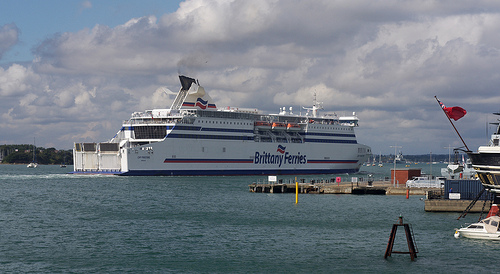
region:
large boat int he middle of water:
[25, 37, 495, 272]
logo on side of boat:
[226, 136, 316, 175]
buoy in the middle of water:
[368, 198, 443, 269]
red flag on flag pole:
[426, 84, 480, 159]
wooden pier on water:
[268, 166, 435, 211]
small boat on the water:
[446, 201, 499, 266]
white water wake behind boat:
[1, 161, 142, 214]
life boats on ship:
[247, 121, 317, 148]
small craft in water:
[7, 155, 50, 179]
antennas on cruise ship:
[279, 76, 339, 122]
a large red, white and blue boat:
[57, 74, 374, 177]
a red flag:
[440, 102, 470, 119]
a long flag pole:
[432, 95, 474, 147]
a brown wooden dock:
[244, 177, 388, 192]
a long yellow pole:
[293, 180, 301, 206]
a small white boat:
[454, 214, 499, 240]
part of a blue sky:
[8, 0, 163, 19]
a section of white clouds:
[0, 62, 111, 142]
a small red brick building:
[390, 167, 420, 186]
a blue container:
[442, 178, 489, 198]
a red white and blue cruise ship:
[82, 75, 369, 177]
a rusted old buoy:
[378, 205, 420, 267]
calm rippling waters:
[83, 194, 265, 266]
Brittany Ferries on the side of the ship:
[249, 137, 321, 167]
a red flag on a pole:
[421, 85, 476, 142]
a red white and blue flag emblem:
[272, 140, 286, 153]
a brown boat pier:
[249, 169, 399, 197]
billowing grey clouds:
[12, 75, 134, 127]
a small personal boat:
[445, 221, 498, 236]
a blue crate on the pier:
[441, 168, 488, 204]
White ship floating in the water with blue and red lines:
[65, 85, 368, 186]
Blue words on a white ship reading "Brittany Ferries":
[249, 150, 311, 167]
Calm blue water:
[44, 184, 263, 259]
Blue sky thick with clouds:
[71, 12, 431, 76]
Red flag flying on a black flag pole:
[433, 93, 473, 121]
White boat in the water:
[457, 214, 499, 239]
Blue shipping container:
[440, 174, 489, 203]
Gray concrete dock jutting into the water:
[245, 168, 388, 203]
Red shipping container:
[383, 155, 415, 184]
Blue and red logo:
[188, 94, 216, 114]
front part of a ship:
[130, 165, 135, 173]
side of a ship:
[223, 140, 243, 165]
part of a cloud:
[268, 29, 276, 41]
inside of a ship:
[303, 123, 320, 129]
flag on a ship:
[196, 93, 208, 108]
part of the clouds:
[63, 55, 87, 77]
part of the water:
[138, 167, 183, 219]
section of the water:
[119, 223, 133, 243]